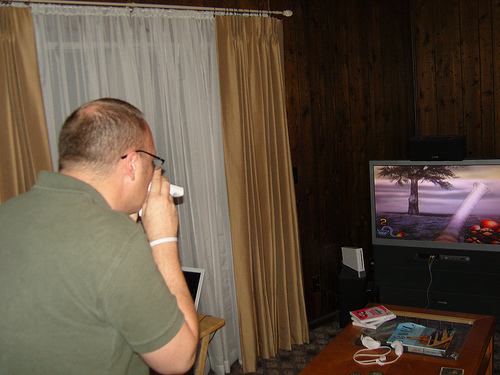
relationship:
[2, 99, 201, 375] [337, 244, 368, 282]
man playing wii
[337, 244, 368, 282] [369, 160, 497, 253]
game on tv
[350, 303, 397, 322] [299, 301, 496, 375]
book on table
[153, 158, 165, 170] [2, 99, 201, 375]
spectacles on man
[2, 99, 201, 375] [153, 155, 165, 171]
man wearing spectacles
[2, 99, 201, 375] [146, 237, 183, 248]
man wearing band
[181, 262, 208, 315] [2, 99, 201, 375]
laptop near man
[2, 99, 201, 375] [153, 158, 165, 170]
man with spectacles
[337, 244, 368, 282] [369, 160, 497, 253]
game on television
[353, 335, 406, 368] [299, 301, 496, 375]
controller on table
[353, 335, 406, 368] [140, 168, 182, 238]
controller in hand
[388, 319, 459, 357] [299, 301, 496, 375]
magazine on table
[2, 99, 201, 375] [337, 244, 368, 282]
man playing game